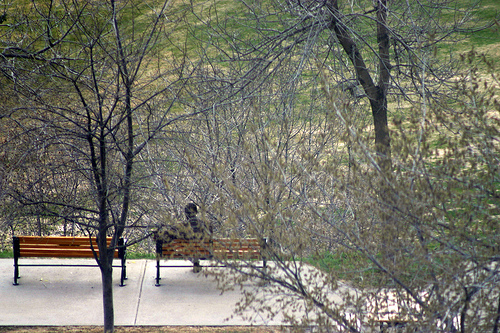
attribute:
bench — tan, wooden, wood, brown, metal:
[18, 223, 136, 290]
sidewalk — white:
[4, 250, 403, 333]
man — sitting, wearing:
[150, 176, 227, 270]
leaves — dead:
[119, 20, 191, 100]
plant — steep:
[369, 213, 495, 318]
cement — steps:
[108, 266, 202, 305]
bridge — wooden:
[174, 312, 265, 330]